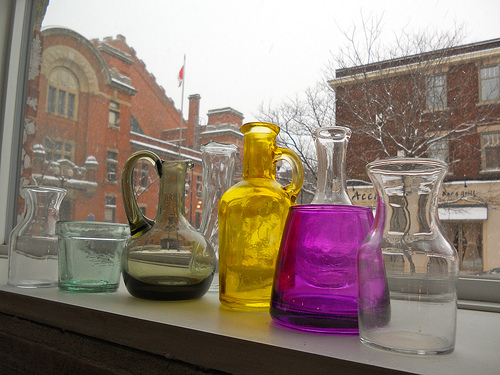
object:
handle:
[271, 147, 304, 203]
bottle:
[188, 141, 241, 293]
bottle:
[293, 124, 374, 290]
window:
[44, 65, 81, 122]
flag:
[176, 65, 185, 88]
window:
[420, 66, 450, 115]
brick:
[77, 95, 143, 179]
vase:
[355, 156, 462, 357]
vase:
[267, 203, 393, 336]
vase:
[216, 121, 304, 313]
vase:
[7, 183, 69, 289]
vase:
[116, 150, 217, 302]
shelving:
[0, 254, 500, 375]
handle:
[119, 150, 163, 241]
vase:
[54, 219, 131, 294]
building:
[12, 25, 245, 232]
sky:
[36, 0, 498, 179]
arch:
[40, 44, 99, 93]